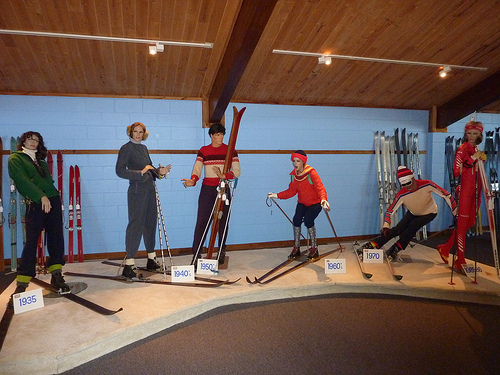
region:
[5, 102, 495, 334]
6 mannequins on display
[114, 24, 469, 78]
light on the ceiling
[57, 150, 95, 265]
red skis leaning on the wall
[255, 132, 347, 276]
mannequin is squatting down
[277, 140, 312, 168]
an orange head band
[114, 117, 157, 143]
a pair of beige ear muffs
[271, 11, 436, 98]
the ceiling is light brown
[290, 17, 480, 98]
the ceiling is made of wood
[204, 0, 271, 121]
the beam is brown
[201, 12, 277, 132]
the beam is made of wood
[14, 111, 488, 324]
six mannequins with skis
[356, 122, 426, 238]
several skis against the wall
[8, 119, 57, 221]
a mannequin wearing a green shirt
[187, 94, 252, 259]
a mannequin holding skis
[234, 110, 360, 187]
a blue block wall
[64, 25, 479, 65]
lights hanging from the cieling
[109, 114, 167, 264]
a mannequin wearing grey clothes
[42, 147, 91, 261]
red skis against the wall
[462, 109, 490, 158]
a mannequin wearing a red head band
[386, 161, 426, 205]
a mannequin wearing a hat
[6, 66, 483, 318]
mannequin on a ski display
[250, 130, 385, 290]
child mannequin with orange ski jacket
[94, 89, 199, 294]
adult mannequin with grey one piece on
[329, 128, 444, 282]
ski stance mannequin with cream sweater with red shoulder and arms.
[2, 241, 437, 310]
five price tag for ski mannequin display items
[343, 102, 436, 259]
multiple pairs of skis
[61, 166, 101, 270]
set of red skis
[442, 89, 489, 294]
female mannequin in red one-piece ski suit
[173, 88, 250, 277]
mannequin holding pair of skis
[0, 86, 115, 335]
mannequin with green jacket and dark pants on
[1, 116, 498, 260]
mannequins display ski wear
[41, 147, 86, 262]
red skies in different sizes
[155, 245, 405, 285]
prices for complete ski outfits and skis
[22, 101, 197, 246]
blue cinder block wall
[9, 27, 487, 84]
two sets of track lighting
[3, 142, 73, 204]
green fleece with navy blue trim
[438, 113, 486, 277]
all red ski outfit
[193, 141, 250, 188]
mens striped sweater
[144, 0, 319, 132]
dark wood beam on pitched ceiling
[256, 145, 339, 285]
youth ski outfit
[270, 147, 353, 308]
Mannequin in Orange jacket.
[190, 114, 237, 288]
Mannequin of a man.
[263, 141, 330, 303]
Mannequin of a girl.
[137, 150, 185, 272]
Ski poles are standing up.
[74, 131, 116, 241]
Blue brick wall in the background.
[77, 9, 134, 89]
Wood stained ceiling above display.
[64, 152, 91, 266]
Red skis against the wall.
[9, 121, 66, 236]
White turtle neck on female mannequin.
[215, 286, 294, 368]
Brown flooring in the room.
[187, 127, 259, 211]
Man's sweater with horizontal stripes.